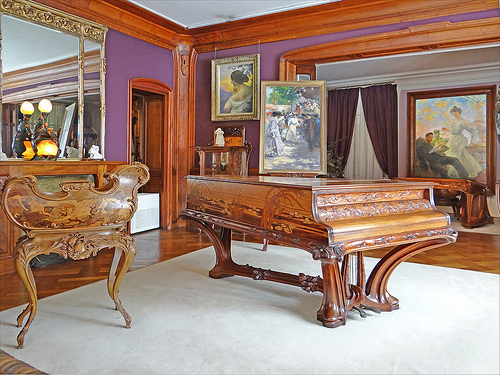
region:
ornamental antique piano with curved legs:
[191, 165, 461, 319]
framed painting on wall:
[399, 83, 496, 190]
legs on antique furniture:
[7, 259, 147, 347]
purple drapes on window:
[321, 78, 406, 180]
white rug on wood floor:
[159, 238, 196, 280]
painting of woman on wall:
[216, 59, 258, 117]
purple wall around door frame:
[109, 50, 170, 92]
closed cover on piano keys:
[337, 207, 441, 263]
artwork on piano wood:
[215, 192, 302, 227]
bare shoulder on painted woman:
[229, 84, 253, 104]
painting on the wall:
[401, 84, 496, 194]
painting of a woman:
[211, 53, 263, 121]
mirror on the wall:
[0, 0, 116, 166]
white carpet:
[0, 234, 491, 374]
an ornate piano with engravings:
[171, 165, 459, 331]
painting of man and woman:
[407, 92, 487, 182]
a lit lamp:
[33, 95, 58, 160]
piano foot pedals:
[350, 293, 385, 320]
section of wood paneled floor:
[457, 233, 494, 264]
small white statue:
[86, 144, 104, 160]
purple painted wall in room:
[109, 50, 171, 73]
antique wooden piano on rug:
[177, 164, 462, 327]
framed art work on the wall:
[394, 80, 499, 199]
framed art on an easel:
[253, 77, 332, 183]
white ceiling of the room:
[142, 2, 262, 20]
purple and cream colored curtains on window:
[328, 79, 408, 178]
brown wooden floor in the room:
[468, 230, 496, 272]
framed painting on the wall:
[205, 50, 266, 125]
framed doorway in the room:
[121, 71, 181, 239]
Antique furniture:
[2, 0, 497, 370]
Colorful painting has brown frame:
[252, 70, 334, 175]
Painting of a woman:
[206, 50, 258, 120]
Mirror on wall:
[0, 5, 112, 165]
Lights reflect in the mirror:
[10, 90, 62, 160]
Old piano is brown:
[172, 156, 467, 332]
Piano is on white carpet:
[154, 164, 498, 373]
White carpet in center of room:
[0, 234, 496, 372]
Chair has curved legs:
[1, 162, 161, 347]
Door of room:
[119, 70, 179, 241]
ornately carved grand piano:
[178, 168, 460, 330]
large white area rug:
[1, 238, 498, 373]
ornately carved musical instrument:
[1, 160, 152, 348]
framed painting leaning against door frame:
[259, 78, 329, 175]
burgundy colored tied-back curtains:
[328, 78, 399, 181]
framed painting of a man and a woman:
[405, 82, 495, 197]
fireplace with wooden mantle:
[0, 159, 128, 278]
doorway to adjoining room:
[124, 75, 176, 237]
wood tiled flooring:
[1, 226, 499, 313]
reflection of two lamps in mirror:
[11, 96, 56, 160]